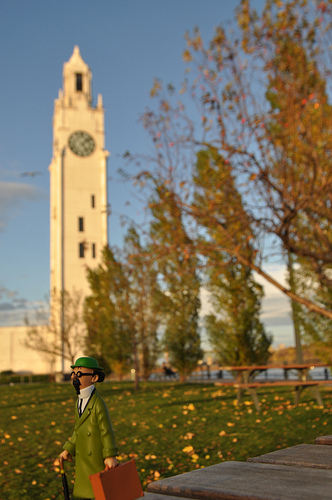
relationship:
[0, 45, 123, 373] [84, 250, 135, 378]
clock tower behind tree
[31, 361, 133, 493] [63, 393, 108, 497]
man wearing coat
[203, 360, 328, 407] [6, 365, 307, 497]
bench on grass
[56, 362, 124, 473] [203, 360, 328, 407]
toy near bench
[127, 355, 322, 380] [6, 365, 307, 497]
water near grass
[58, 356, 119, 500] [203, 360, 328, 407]
man on bench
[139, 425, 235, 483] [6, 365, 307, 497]
leaves on grass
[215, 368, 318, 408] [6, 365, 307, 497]
table in grass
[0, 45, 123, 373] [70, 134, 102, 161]
clock tower has clock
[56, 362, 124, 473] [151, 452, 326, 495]
toy on sidewalk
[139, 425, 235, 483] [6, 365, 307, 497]
leaves in grass